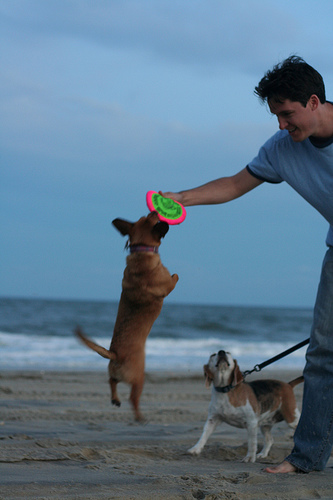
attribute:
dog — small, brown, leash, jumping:
[93, 189, 200, 353]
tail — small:
[54, 301, 135, 375]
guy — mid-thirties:
[194, 48, 332, 273]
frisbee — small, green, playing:
[152, 178, 197, 233]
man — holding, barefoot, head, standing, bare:
[228, 56, 331, 227]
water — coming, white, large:
[0, 285, 96, 343]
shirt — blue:
[284, 152, 325, 185]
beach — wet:
[3, 364, 87, 481]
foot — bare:
[262, 420, 331, 479]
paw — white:
[171, 260, 189, 294]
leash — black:
[246, 318, 318, 381]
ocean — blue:
[13, 291, 78, 339]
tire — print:
[14, 421, 84, 490]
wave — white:
[17, 341, 79, 378]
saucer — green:
[148, 191, 199, 224]